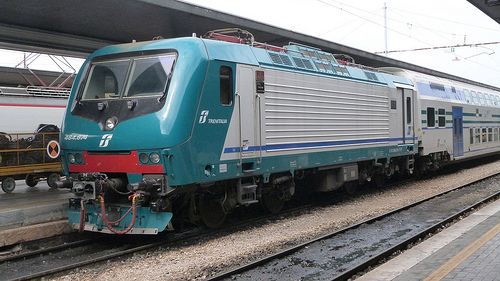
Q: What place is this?
A: It is a station.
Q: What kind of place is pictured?
A: It is a station.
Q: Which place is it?
A: It is a station.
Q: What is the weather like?
A: It is overcast.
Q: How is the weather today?
A: It is overcast.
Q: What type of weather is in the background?
A: It is overcast.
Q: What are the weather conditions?
A: It is overcast.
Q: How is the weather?
A: It is overcast.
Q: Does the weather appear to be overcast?
A: Yes, it is overcast.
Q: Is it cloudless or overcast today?
A: It is overcast.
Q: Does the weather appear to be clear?
A: No, it is overcast.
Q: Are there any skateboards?
A: No, there are no skateboards.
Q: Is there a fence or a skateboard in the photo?
A: No, there are no skateboards or fences.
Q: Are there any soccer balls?
A: No, there are no soccer balls.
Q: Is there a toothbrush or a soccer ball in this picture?
A: No, there are no soccer balls or toothbrushes.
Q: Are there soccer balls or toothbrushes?
A: No, there are no soccer balls or toothbrushes.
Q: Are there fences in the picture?
A: No, there are no fences.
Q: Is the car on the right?
A: Yes, the car is on the right of the image.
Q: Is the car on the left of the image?
A: No, the car is on the right of the image.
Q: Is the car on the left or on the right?
A: The car is on the right of the image.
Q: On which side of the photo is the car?
A: The car is on the right of the image.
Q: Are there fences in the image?
A: No, there are no fences.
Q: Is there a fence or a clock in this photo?
A: No, there are no fences or clocks.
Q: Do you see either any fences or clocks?
A: No, there are no fences or clocks.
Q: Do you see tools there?
A: No, there are no tools.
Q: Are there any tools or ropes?
A: No, there are no tools or ropes.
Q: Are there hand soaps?
A: No, there are no hand soaps.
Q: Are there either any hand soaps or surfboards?
A: No, there are no hand soaps or surfboards.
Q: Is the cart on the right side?
A: No, the cart is on the left of the image.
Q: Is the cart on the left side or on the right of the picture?
A: The cart is on the left of the image.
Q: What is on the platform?
A: The cart is on the platform.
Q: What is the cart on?
A: The cart is on the platform.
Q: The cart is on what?
A: The cart is on the platform.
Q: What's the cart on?
A: The cart is on the platform.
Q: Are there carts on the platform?
A: Yes, there is a cart on the platform.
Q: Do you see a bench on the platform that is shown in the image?
A: No, there is a cart on the platform.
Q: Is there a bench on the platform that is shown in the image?
A: No, there is a cart on the platform.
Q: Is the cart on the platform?
A: Yes, the cart is on the platform.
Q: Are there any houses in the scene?
A: No, there are no houses.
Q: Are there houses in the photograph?
A: No, there are no houses.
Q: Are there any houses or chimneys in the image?
A: No, there are no houses or chimneys.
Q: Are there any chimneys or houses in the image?
A: No, there are no houses or chimneys.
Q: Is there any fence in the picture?
A: No, there are no fences.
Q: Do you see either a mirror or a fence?
A: No, there are no fences or mirrors.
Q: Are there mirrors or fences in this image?
A: No, there are no fences or mirrors.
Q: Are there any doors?
A: Yes, there is a door.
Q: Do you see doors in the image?
A: Yes, there is a door.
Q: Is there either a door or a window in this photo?
A: Yes, there is a door.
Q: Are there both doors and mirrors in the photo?
A: No, there is a door but no mirrors.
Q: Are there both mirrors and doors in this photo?
A: No, there is a door but no mirrors.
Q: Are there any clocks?
A: No, there are no clocks.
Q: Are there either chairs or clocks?
A: No, there are no clocks or chairs.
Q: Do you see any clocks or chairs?
A: No, there are no clocks or chairs.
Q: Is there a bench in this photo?
A: No, there are no benches.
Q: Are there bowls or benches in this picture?
A: No, there are no benches or bowls.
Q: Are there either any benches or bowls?
A: No, there are no benches or bowls.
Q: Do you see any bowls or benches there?
A: No, there are no benches or bowls.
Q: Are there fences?
A: No, there are no fences.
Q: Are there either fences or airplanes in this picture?
A: No, there are no fences or airplanes.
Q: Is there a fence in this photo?
A: No, there are no fences.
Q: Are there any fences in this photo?
A: No, there are no fences.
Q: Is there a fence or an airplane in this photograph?
A: No, there are no fences or airplanes.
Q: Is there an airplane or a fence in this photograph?
A: No, there are no fences or airplanes.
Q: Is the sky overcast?
A: Yes, the sky is overcast.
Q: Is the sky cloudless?
A: No, the sky is overcast.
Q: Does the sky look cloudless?
A: No, the sky is overcast.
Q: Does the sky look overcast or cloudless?
A: The sky is overcast.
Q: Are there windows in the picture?
A: Yes, there are windows.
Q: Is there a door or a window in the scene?
A: Yes, there are windows.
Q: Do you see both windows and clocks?
A: No, there are windows but no clocks.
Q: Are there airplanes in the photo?
A: No, there are no airplanes.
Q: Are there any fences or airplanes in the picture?
A: No, there are no airplanes or fences.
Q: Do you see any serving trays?
A: No, there are no serving trays.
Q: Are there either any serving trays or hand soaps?
A: No, there are no serving trays or hand soaps.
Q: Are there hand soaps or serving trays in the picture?
A: No, there are no serving trays or hand soaps.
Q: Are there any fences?
A: No, there are no fences.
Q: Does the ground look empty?
A: Yes, the ground is empty.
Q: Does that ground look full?
A: No, the ground is empty.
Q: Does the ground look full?
A: No, the ground is empty.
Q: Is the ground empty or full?
A: The ground is empty.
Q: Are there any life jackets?
A: No, there are no life jackets.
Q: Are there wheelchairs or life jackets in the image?
A: No, there are no life jackets or wheelchairs.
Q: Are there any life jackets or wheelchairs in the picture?
A: No, there are no life jackets or wheelchairs.